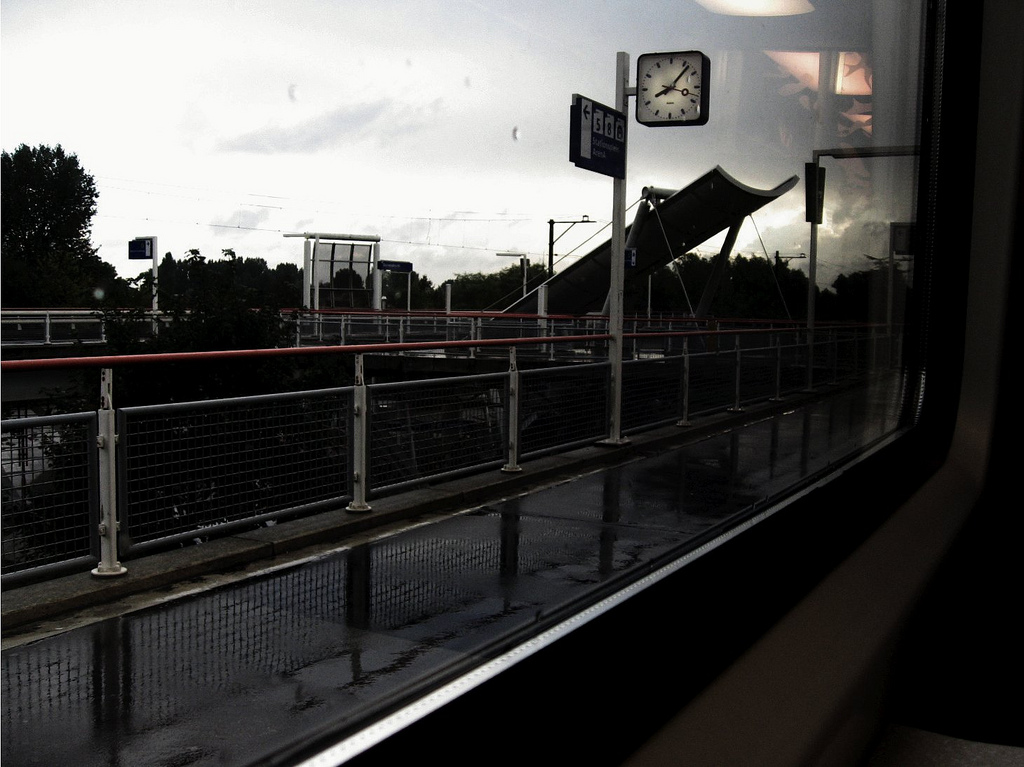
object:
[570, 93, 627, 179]
sign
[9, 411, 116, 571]
fence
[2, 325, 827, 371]
railing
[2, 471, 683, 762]
reflection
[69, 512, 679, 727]
water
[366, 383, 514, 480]
fence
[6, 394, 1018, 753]
ground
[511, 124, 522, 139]
drop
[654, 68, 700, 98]
hands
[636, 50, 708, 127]
clock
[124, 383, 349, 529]
fence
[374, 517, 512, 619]
fence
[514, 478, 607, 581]
fence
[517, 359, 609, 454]
fence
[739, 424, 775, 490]
fence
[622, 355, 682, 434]
fence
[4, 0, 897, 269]
sky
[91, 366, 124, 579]
pole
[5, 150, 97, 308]
bush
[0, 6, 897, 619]
scene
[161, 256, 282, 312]
trees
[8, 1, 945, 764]
window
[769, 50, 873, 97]
light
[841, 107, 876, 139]
light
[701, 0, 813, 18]
light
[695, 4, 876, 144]
reflection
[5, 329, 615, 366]
top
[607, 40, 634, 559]
pole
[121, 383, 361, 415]
rail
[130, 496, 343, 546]
rail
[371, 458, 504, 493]
rail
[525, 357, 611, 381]
rail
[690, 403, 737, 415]
rail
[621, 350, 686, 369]
rail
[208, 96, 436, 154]
clouds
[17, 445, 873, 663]
pavement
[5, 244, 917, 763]
train station